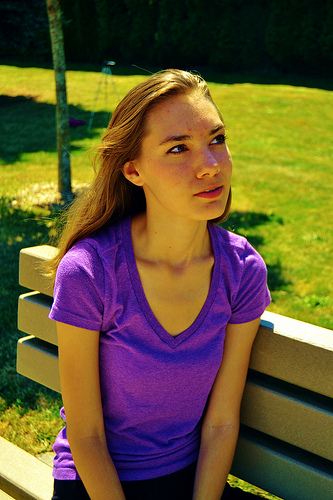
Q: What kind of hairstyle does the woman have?
A: Long straight auburn hair.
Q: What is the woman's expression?
A: Enigmatic.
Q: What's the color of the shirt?
A: Purple.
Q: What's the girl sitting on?
A: Bench.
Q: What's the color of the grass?
A: Green.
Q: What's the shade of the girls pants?
A: Dark.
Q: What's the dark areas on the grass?
A: Shade.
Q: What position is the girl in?
A: Sitting.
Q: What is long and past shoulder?
A: The hair of the girl.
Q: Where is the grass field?
A: Behind the girl.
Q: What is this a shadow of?
A: The trees.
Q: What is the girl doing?
A: Looking up and to the right.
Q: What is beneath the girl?
A: Brown bench.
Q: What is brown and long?
A: Brown hair of the girl.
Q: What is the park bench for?
A: To sit on.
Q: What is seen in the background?
A: Bright green grass.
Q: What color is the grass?
A: Green.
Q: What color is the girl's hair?
A: Brown.